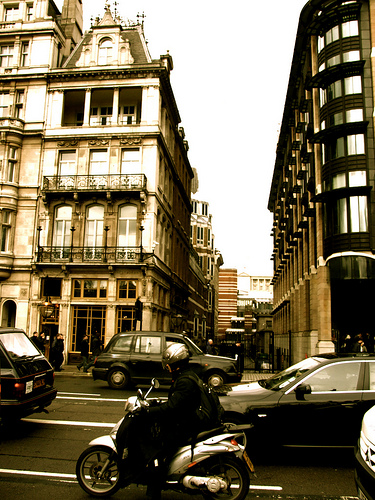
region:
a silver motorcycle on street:
[78, 387, 254, 495]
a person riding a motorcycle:
[78, 335, 253, 493]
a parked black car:
[87, 326, 239, 388]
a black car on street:
[202, 349, 373, 453]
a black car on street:
[0, 323, 62, 426]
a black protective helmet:
[157, 335, 188, 365]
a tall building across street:
[265, 3, 367, 359]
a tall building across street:
[0, 0, 190, 338]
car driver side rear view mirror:
[293, 379, 312, 396]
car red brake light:
[12, 379, 22, 391]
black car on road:
[91, 319, 238, 377]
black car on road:
[220, 351, 363, 456]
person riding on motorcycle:
[84, 349, 253, 495]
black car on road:
[0, 324, 70, 440]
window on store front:
[117, 200, 144, 258]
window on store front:
[83, 201, 105, 255]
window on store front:
[53, 198, 71, 250]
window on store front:
[111, 140, 144, 184]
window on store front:
[81, 147, 107, 183]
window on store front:
[54, 150, 75, 192]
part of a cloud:
[217, 205, 233, 234]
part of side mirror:
[294, 373, 313, 409]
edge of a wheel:
[238, 474, 251, 489]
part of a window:
[313, 372, 340, 392]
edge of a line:
[276, 486, 284, 495]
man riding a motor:
[93, 339, 276, 489]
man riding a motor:
[78, 345, 179, 432]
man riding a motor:
[19, 245, 254, 478]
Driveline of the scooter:
[179, 466, 233, 494]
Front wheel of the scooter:
[70, 443, 126, 497]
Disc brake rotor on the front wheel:
[88, 459, 111, 484]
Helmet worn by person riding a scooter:
[163, 341, 189, 373]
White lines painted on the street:
[6, 462, 69, 482]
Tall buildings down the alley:
[217, 266, 272, 358]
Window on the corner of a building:
[322, 193, 373, 242]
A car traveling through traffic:
[90, 329, 246, 385]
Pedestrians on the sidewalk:
[78, 331, 104, 382]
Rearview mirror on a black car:
[295, 381, 312, 402]